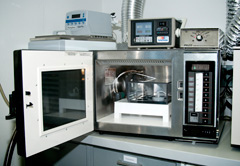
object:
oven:
[4, 49, 225, 160]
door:
[13, 50, 95, 159]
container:
[124, 81, 172, 105]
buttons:
[188, 72, 208, 125]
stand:
[26, 121, 239, 166]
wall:
[1, 0, 227, 166]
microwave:
[185, 61, 214, 127]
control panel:
[184, 61, 215, 128]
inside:
[97, 62, 172, 128]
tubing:
[122, 1, 240, 57]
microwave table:
[114, 100, 172, 121]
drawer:
[93, 148, 178, 166]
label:
[123, 155, 138, 164]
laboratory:
[0, 1, 239, 166]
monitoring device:
[128, 18, 183, 49]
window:
[41, 68, 86, 132]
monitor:
[180, 28, 227, 51]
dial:
[196, 34, 203, 41]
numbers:
[190, 30, 210, 44]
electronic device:
[65, 9, 92, 39]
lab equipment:
[5, 10, 228, 158]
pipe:
[3, 129, 18, 166]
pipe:
[1, 85, 10, 108]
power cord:
[224, 70, 232, 123]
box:
[230, 46, 239, 148]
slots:
[177, 81, 184, 102]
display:
[192, 63, 210, 72]